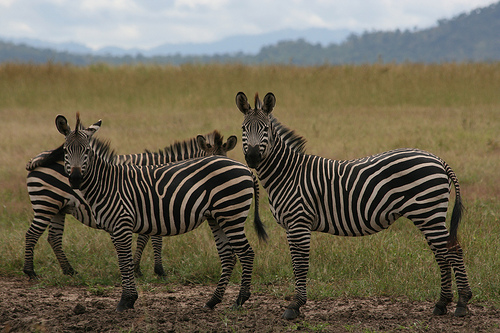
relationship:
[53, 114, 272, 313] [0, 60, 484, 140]
zebra standing in a field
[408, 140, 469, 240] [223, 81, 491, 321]
end of zebra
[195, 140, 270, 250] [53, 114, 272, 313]
end of zebra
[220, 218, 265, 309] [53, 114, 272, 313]
leg of zebra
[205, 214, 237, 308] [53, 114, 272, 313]
leg of zebra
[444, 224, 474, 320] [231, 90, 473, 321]
leg of zebra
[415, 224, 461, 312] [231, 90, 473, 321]
leg of zebra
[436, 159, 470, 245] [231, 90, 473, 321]
tail of a zebra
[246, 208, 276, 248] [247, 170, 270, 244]
tuft on tail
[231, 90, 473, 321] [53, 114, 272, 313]
zebra standing with zebra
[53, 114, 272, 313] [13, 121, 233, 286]
zebra standing with zebra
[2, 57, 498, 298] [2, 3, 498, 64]
grassland with mountains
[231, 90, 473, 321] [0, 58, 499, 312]
zebra standing near grassland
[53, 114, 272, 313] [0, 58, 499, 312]
zebra standing near grassland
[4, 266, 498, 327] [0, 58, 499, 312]
dirt near grassland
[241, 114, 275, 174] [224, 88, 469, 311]
face of zebra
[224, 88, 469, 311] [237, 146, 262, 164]
zebra with nose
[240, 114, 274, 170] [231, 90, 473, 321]
face of zebra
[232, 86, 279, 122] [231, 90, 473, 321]
ears of zebra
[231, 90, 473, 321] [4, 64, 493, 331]
zebra in plain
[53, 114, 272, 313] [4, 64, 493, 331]
zebra in plain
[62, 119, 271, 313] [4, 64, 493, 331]
zebra in plain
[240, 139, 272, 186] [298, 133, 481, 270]
nose on zebra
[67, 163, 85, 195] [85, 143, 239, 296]
nose on zebra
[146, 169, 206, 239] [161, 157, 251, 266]
stripe on zebra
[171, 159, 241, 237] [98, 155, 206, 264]
stripe on zebra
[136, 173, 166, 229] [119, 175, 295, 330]
stripe on zebra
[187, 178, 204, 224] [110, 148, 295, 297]
stripe on zebra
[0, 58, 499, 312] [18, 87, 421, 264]
grassland behind zebra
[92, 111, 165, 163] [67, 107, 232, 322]
mane on zebra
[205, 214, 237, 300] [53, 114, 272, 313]
leg on zebra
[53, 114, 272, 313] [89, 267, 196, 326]
zebra on grass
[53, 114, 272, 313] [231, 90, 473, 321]
zebra behind zebra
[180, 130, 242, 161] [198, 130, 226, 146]
zebra head has a hair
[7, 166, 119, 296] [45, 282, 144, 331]
zebra on grass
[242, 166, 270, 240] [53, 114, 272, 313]
tail on back of zebra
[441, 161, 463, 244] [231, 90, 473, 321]
tail apart zebra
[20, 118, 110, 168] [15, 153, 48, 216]
tail on back of behind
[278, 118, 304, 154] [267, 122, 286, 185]
hair on back of neck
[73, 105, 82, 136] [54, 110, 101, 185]
hair on top of head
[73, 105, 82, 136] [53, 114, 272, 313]
hair on zebra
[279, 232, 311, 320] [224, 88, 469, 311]
leg apart of zebra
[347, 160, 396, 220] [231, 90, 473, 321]
stripe of zebra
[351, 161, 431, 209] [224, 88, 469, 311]
stripe of zebra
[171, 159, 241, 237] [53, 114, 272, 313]
stripe of zebra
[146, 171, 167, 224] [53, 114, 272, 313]
stripe of zebra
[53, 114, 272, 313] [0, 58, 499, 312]
zebra on grassland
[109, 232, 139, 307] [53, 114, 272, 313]
leg on zebra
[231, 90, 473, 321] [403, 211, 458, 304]
zebra on leg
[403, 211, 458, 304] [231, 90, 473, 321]
leg on zebra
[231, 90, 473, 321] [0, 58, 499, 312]
zebra on grassland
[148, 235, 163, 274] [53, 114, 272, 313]
leg on zebra